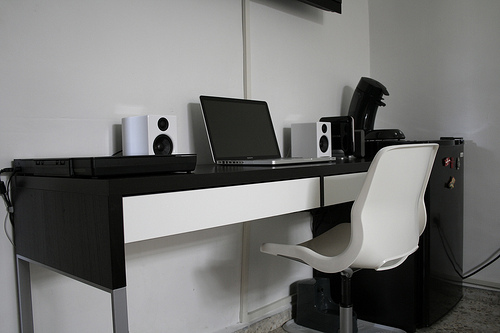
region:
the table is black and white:
[93, 204, 123, 244]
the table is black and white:
[130, 210, 144, 227]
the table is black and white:
[113, 217, 128, 232]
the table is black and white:
[99, 194, 119, 211]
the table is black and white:
[90, 202, 125, 229]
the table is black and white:
[110, 205, 127, 222]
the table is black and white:
[115, 205, 135, 232]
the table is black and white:
[105, 209, 126, 231]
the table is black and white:
[120, 205, 135, 232]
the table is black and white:
[113, 221, 127, 242]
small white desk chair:
[251, 125, 445, 330]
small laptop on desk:
[184, 75, 349, 181]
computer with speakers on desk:
[104, 79, 364, 177]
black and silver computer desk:
[3, 146, 477, 331]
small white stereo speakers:
[113, 103, 197, 178]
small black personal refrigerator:
[338, 97, 476, 330]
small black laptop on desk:
[5, 140, 206, 203]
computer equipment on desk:
[4, 67, 496, 332]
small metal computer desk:
[3, 145, 446, 331]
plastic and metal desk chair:
[259, 132, 454, 330]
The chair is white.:
[251, 136, 449, 331]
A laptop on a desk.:
[4, 81, 488, 331]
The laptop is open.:
[189, 85, 339, 182]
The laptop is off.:
[188, 92, 343, 182]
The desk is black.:
[3, 95, 480, 329]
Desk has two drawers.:
[12, 103, 485, 329]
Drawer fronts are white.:
[7, 87, 475, 332]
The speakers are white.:
[110, 102, 349, 202]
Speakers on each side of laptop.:
[107, 77, 354, 194]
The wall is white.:
[2, 2, 499, 332]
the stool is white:
[381, 220, 387, 232]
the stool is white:
[376, 214, 387, 242]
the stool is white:
[382, 217, 392, 245]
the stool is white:
[384, 223, 391, 264]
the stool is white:
[395, 214, 404, 257]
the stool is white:
[395, 231, 405, 246]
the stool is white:
[379, 241, 385, 252]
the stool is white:
[384, 239, 393, 251]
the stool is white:
[376, 230, 384, 260]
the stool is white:
[372, 220, 379, 257]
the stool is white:
[390, 223, 400, 254]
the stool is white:
[370, 239, 379, 258]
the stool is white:
[383, 220, 390, 240]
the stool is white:
[376, 203, 383, 240]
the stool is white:
[387, 221, 394, 251]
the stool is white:
[374, 210, 381, 240]